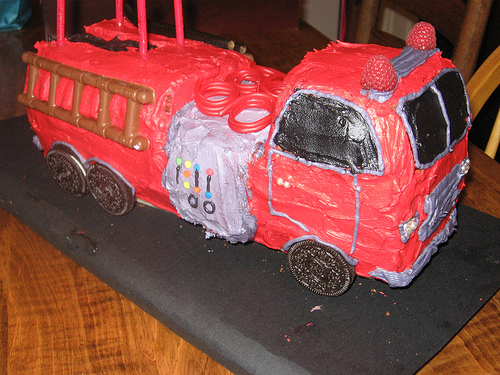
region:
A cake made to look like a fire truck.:
[16, 1, 471, 297]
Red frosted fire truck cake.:
[15, 0, 470, 295]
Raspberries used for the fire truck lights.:
[361, 22, 437, 92]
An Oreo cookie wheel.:
[286, 238, 353, 298]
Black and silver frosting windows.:
[268, 67, 468, 175]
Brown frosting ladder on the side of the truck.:
[13, 54, 153, 152]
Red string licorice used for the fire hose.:
[196, 65, 284, 135]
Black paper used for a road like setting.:
[1, 118, 498, 373]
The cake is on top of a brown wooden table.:
[0, 0, 499, 374]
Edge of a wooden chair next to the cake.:
[461, 42, 499, 160]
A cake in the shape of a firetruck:
[20, 19, 482, 302]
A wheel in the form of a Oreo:
[273, 225, 361, 304]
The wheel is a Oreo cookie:
[282, 231, 359, 306]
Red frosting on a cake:
[297, 172, 345, 217]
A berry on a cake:
[360, 55, 399, 90]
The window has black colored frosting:
[293, 100, 371, 171]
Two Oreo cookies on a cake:
[41, 142, 143, 223]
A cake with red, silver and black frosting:
[158, 132, 336, 209]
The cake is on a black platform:
[151, 170, 369, 322]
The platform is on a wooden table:
[16, 290, 187, 367]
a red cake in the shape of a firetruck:
[13, 6, 498, 370]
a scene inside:
[10, 11, 495, 373]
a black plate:
[9, 112, 494, 367]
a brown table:
[3, 55, 497, 373]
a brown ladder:
[5, 35, 175, 165]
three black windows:
[252, 53, 482, 190]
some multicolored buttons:
[166, 149, 223, 201]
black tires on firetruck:
[39, 131, 373, 315]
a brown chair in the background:
[306, 0, 496, 135]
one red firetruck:
[12, 6, 489, 317]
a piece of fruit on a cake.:
[353, 45, 408, 104]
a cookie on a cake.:
[278, 229, 360, 301]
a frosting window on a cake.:
[269, 90, 388, 182]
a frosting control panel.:
[159, 121, 254, 236]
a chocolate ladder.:
[7, 49, 159, 163]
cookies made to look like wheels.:
[34, 133, 157, 236]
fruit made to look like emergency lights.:
[351, 14, 447, 109]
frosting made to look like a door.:
[274, 174, 289, 194]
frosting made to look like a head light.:
[388, 208, 426, 243]